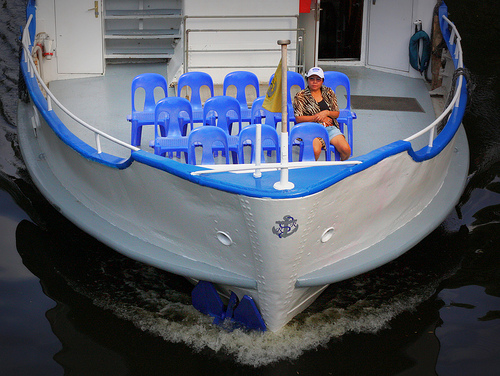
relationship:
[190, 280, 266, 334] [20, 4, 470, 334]
anchor on boat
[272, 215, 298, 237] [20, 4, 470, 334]
logo on boat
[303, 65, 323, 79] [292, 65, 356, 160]
hat on woman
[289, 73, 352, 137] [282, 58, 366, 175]
shirt on woman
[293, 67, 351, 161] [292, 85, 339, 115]
person wearing shirt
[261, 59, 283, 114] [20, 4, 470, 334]
flag on boat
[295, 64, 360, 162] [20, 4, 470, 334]
person on boat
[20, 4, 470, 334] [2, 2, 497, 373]
boat on river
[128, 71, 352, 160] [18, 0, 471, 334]
chairs in front of boat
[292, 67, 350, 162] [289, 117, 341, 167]
woman sitting on blue chair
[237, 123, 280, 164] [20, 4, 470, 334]
chair on boat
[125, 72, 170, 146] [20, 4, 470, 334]
blue chair on boat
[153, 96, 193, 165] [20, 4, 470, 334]
chair on boat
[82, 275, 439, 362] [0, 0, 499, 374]
wave in water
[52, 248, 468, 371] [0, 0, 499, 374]
ripples in water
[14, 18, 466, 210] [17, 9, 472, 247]
rim of boat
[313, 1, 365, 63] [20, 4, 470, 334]
door built into boat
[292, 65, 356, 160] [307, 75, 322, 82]
woman wearing sunglasses